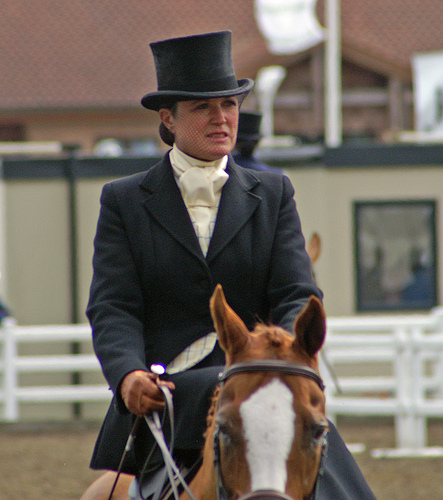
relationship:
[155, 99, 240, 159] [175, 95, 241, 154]
netting over person's face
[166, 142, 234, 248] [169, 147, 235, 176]
tie around neck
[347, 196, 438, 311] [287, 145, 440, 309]
picture on wall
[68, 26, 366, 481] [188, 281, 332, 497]
lady riding horse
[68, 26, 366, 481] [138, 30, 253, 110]
lady wearing hat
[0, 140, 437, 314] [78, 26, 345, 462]
building behind lady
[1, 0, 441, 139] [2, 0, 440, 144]
roof of building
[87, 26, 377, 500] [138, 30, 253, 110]
lady wearing hat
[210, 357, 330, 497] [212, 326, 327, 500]
dark straps on face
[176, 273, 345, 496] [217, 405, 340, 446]
horse has eyes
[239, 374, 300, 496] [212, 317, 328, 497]
marking on face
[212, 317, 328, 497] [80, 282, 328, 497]
face on horse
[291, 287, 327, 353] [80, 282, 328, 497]
ear on horse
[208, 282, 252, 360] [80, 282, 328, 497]
ear on horse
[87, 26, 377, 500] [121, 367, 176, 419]
lady wearing glove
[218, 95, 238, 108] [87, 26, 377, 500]
eye on lady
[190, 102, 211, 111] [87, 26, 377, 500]
eye on lady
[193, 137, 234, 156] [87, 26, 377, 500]
chin on lady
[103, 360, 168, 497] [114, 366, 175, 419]
riding whip in hand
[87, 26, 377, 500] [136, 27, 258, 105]
lady wearing top hat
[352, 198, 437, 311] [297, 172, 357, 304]
picture on wall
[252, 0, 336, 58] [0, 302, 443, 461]
flag behind fence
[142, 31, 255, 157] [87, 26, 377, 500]
head of lady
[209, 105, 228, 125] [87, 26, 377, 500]
nose of lady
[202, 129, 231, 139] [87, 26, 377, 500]
lips of lady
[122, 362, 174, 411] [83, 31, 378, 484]
hand of woman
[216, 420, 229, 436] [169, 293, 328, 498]
eye of horse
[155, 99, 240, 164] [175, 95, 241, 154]
netting over person's face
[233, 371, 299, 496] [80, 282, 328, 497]
coloring on horse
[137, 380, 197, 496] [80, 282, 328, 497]
reigns attached to horse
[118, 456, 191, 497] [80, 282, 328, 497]
saddle on horse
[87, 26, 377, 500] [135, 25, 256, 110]
lady wearing hat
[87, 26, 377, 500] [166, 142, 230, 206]
lady wearing tie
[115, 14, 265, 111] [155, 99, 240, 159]
hat with netting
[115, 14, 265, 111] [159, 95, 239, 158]
hat atop head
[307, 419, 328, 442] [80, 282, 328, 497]
eye of horse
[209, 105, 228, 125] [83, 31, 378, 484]
nose of woman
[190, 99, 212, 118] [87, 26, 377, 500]
eye of lady